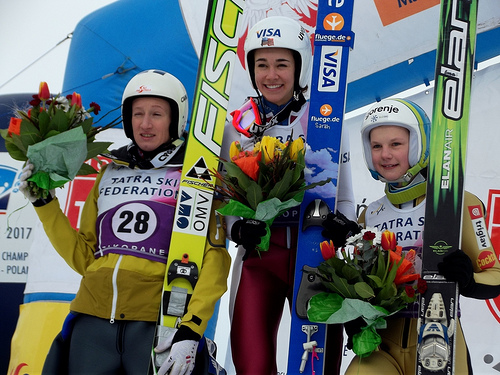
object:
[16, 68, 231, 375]
people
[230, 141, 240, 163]
flowers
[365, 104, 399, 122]
logo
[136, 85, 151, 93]
logo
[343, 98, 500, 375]
girl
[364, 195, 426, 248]
shirt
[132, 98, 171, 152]
face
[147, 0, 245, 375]
ski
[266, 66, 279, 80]
nose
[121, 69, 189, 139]
helmet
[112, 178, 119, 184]
letter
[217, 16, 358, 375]
lady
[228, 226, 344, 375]
red pants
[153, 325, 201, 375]
glove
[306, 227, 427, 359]
flower bouquet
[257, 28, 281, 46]
logo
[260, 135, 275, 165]
flower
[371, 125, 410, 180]
face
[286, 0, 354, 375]
blue ski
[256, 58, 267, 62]
eyebrows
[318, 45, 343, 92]
logo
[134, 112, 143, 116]
eye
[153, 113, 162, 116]
eye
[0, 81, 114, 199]
flowers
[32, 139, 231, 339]
jacket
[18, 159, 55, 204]
woman's hand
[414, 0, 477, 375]
skis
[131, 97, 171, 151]
head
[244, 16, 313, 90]
helmet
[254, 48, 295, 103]
head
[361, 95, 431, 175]
helmet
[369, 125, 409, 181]
head